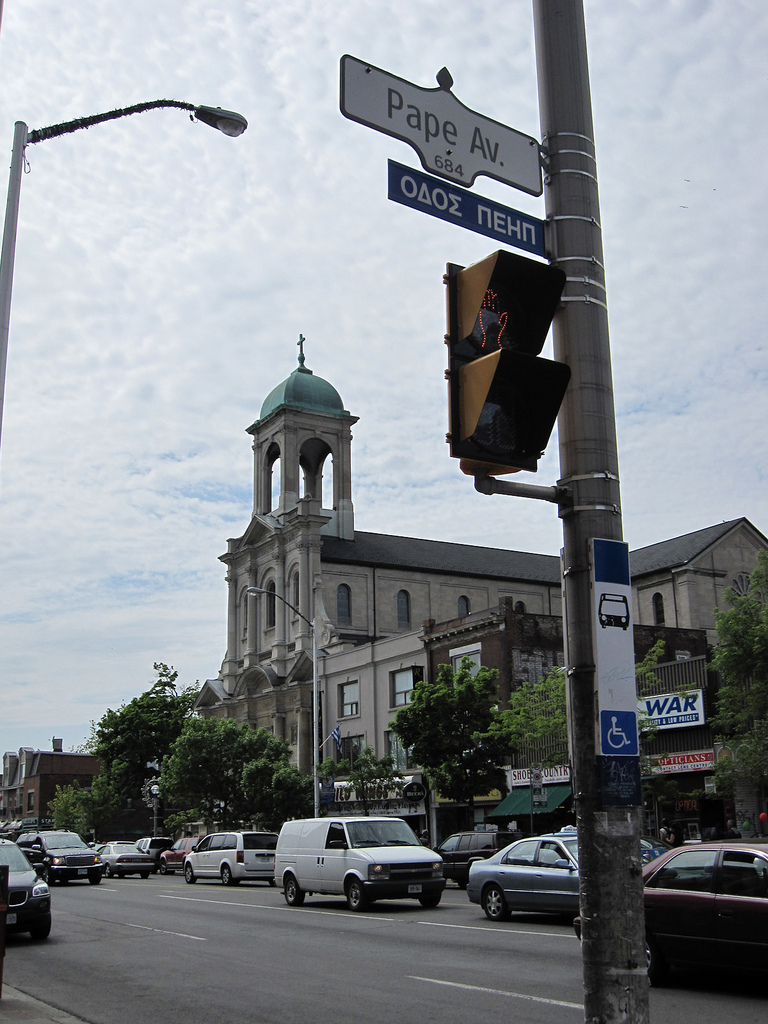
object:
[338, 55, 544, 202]
sign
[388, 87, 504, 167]
pape av.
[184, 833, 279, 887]
van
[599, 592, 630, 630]
bus outline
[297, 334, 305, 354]
cross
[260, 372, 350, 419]
dome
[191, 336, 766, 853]
building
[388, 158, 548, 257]
sign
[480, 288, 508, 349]
hand symbol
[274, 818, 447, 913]
van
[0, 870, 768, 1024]
street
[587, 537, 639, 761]
sign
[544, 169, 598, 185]
brackets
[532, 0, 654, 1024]
pole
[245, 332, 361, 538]
belfry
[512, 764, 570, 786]
sign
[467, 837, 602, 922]
car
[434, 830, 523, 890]
car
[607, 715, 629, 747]
handicap sign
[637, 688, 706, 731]
sign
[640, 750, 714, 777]
sign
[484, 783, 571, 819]
awning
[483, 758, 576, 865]
storefront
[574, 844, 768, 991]
car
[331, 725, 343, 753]
flag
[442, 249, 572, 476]
crosswalk sign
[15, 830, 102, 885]
vehicle